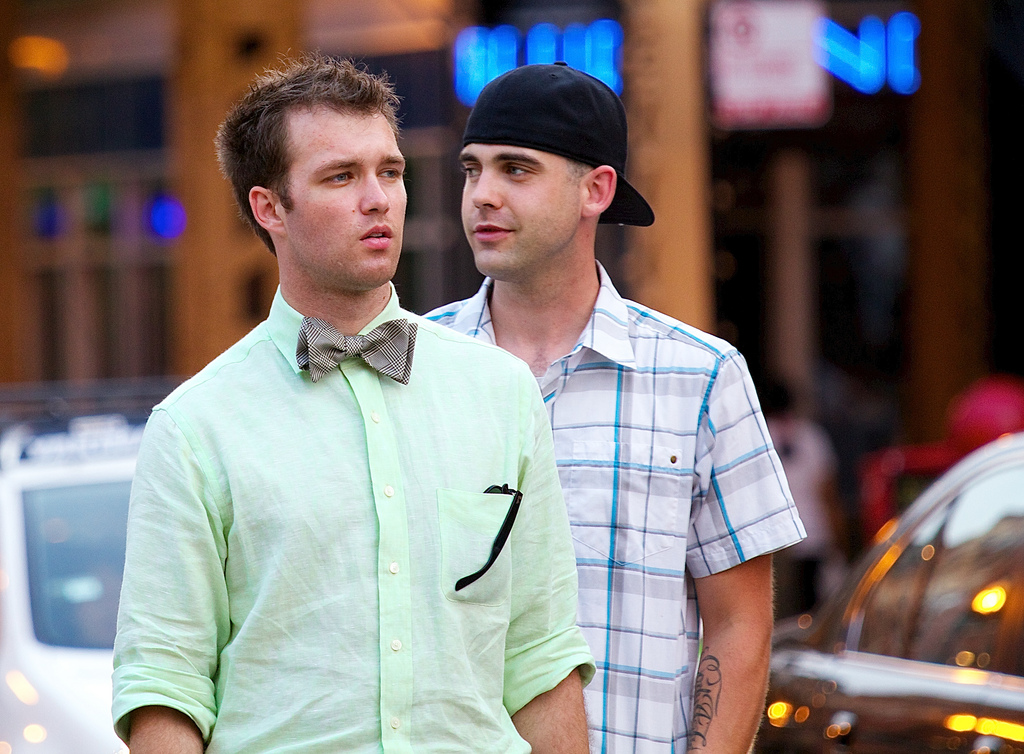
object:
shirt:
[418, 259, 806, 754]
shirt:
[110, 280, 594, 754]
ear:
[249, 186, 286, 236]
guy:
[110, 46, 596, 754]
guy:
[419, 62, 806, 754]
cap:
[463, 61, 655, 227]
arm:
[690, 350, 776, 752]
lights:
[767, 432, 1024, 752]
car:
[751, 433, 1023, 754]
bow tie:
[296, 316, 418, 385]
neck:
[280, 279, 392, 337]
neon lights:
[455, 11, 922, 107]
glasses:
[455, 484, 523, 592]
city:
[0, 0, 1024, 754]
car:
[0, 412, 145, 754]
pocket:
[438, 486, 515, 607]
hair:
[212, 46, 413, 257]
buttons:
[371, 412, 402, 729]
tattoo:
[687, 646, 722, 750]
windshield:
[21, 479, 130, 649]